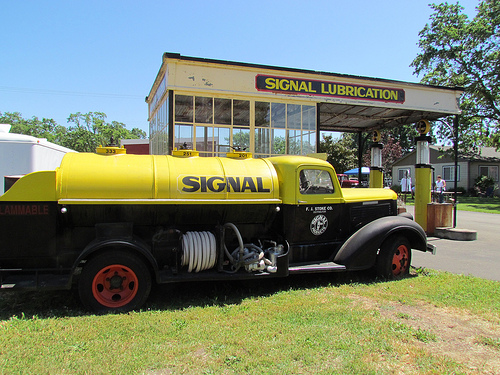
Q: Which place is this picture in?
A: It is at the station.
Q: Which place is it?
A: It is a station.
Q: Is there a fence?
A: No, there are no fences.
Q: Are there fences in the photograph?
A: No, there are no fences.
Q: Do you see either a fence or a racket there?
A: No, there are no fences or rackets.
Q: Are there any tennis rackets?
A: No, there are no tennis rackets.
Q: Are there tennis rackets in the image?
A: No, there are no tennis rackets.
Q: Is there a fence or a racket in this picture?
A: No, there are no rackets or fences.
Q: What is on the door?
A: The logo is on the door.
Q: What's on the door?
A: The logo is on the door.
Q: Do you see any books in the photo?
A: No, there are no books.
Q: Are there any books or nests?
A: No, there are no books or nests.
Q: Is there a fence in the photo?
A: No, there are no fences.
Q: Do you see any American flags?
A: No, there are no American flags.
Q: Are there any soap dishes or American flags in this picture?
A: No, there are no American flags or soap dishes.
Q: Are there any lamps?
A: No, there are no lamps.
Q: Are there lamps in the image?
A: No, there are no lamps.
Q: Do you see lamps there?
A: No, there are no lamps.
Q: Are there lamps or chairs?
A: No, there are no lamps or chairs.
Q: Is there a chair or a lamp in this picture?
A: No, there are no lamps or chairs.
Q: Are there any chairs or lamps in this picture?
A: No, there are no lamps or chairs.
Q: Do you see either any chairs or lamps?
A: No, there are no lamps or chairs.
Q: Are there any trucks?
A: Yes, there is a truck.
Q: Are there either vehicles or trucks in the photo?
A: Yes, there is a truck.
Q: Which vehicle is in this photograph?
A: The vehicle is a truck.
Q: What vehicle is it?
A: The vehicle is a truck.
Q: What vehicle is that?
A: This is a truck.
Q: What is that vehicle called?
A: This is a truck.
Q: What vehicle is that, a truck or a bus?
A: This is a truck.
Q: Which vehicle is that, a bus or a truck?
A: This is a truck.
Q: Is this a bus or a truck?
A: This is a truck.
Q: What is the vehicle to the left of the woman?
A: The vehicle is a truck.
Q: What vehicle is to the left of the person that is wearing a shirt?
A: The vehicle is a truck.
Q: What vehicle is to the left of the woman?
A: The vehicle is a truck.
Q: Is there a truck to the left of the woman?
A: Yes, there is a truck to the left of the woman.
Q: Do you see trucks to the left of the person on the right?
A: Yes, there is a truck to the left of the woman.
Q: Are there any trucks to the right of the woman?
A: No, the truck is to the left of the woman.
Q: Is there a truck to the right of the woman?
A: No, the truck is to the left of the woman.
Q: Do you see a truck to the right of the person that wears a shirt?
A: No, the truck is to the left of the woman.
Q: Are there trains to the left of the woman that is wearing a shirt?
A: No, there is a truck to the left of the woman.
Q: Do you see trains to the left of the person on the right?
A: No, there is a truck to the left of the woman.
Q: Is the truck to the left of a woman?
A: Yes, the truck is to the left of a woman.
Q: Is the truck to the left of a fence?
A: No, the truck is to the left of a woman.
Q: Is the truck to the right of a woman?
A: No, the truck is to the left of a woman.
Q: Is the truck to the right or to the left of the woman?
A: The truck is to the left of the woman.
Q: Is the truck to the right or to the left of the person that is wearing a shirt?
A: The truck is to the left of the woman.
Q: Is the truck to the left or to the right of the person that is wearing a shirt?
A: The truck is to the left of the woman.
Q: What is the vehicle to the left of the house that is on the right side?
A: The vehicle is a truck.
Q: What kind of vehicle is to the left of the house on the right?
A: The vehicle is a truck.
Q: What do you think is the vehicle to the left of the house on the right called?
A: The vehicle is a truck.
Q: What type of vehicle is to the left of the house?
A: The vehicle is a truck.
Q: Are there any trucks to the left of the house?
A: Yes, there is a truck to the left of the house.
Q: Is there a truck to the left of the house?
A: Yes, there is a truck to the left of the house.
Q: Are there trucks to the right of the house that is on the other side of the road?
A: No, the truck is to the left of the house.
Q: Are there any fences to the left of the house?
A: No, there is a truck to the left of the house.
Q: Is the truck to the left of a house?
A: Yes, the truck is to the left of a house.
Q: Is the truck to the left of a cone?
A: No, the truck is to the left of a house.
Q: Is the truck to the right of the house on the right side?
A: No, the truck is to the left of the house.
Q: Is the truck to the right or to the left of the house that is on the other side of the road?
A: The truck is to the left of the house.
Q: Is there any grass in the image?
A: Yes, there is grass.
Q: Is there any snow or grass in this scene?
A: Yes, there is grass.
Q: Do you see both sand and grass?
A: No, there is grass but no sand.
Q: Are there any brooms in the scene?
A: No, there are no brooms.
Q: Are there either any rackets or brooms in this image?
A: No, there are no brooms or rackets.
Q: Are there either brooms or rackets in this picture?
A: No, there are no brooms or rackets.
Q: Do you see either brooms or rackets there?
A: No, there are no brooms or rackets.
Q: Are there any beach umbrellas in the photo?
A: No, there are no beach umbrellas.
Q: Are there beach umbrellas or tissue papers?
A: No, there are no beach umbrellas or tissue papers.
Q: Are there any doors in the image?
A: Yes, there is a door.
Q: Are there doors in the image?
A: Yes, there is a door.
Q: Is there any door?
A: Yes, there is a door.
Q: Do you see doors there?
A: Yes, there is a door.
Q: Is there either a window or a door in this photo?
A: Yes, there is a door.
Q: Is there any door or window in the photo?
A: Yes, there is a door.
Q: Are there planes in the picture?
A: No, there are no planes.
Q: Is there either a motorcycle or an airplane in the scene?
A: No, there are no airplanes or motorcycles.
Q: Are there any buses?
A: No, there are no buses.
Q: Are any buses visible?
A: No, there are no buses.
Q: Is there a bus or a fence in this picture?
A: No, there are no buses or fences.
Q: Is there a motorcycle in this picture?
A: No, there are no motorcycles.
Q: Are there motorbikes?
A: No, there are no motorbikes.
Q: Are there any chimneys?
A: No, there are no chimneys.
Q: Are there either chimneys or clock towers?
A: No, there are no chimneys or clock towers.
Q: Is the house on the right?
A: Yes, the house is on the right of the image.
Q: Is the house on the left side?
A: No, the house is on the right of the image.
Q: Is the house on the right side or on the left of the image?
A: The house is on the right of the image.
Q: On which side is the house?
A: The house is on the right of the image.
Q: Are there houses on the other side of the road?
A: Yes, there is a house on the other side of the road.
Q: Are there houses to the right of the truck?
A: Yes, there is a house to the right of the truck.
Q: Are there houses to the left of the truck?
A: No, the house is to the right of the truck.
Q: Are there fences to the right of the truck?
A: No, there is a house to the right of the truck.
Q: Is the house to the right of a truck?
A: Yes, the house is to the right of a truck.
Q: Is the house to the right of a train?
A: No, the house is to the right of a truck.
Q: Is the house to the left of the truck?
A: No, the house is to the right of the truck.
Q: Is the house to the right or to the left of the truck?
A: The house is to the right of the truck.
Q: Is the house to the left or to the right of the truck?
A: The house is to the right of the truck.